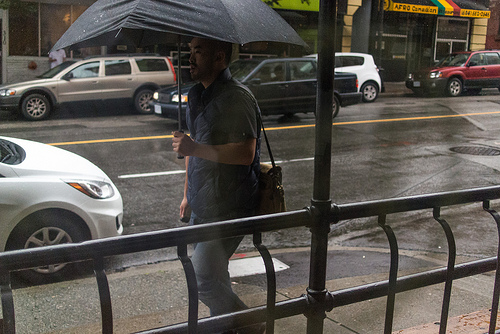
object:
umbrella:
[49, 1, 313, 56]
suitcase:
[186, 85, 286, 220]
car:
[0, 136, 126, 287]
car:
[0, 53, 178, 122]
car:
[149, 58, 362, 125]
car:
[402, 49, 497, 99]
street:
[0, 86, 499, 333]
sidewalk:
[0, 199, 499, 334]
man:
[168, 34, 270, 333]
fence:
[0, 184, 498, 333]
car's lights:
[150, 90, 165, 101]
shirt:
[185, 70, 264, 226]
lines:
[117, 156, 317, 181]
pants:
[185, 216, 256, 330]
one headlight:
[5, 89, 15, 99]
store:
[339, 0, 491, 84]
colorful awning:
[380, 0, 491, 21]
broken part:
[113, 26, 127, 40]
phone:
[180, 201, 191, 225]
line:
[44, 109, 499, 146]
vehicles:
[271, 53, 383, 105]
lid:
[225, 254, 289, 279]